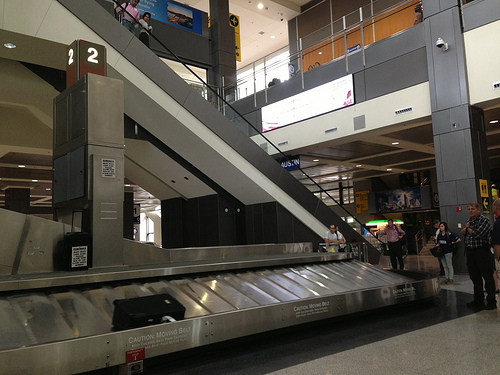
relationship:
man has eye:
[455, 201, 496, 310] [465, 205, 470, 212]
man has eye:
[455, 201, 496, 310] [470, 205, 477, 213]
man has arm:
[459, 201, 496, 310] [456, 217, 491, 234]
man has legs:
[455, 201, 496, 310] [464, 247, 495, 302]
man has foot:
[459, 201, 496, 310] [465, 297, 495, 314]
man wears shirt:
[459, 201, 496, 310] [457, 212, 497, 252]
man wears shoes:
[459, 201, 496, 310] [464, 296, 498, 312]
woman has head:
[437, 221, 456, 286] [437, 222, 447, 232]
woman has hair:
[437, 221, 456, 286] [427, 199, 450, 231]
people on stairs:
[324, 222, 349, 252] [274, 146, 493, 328]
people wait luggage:
[324, 202, 499, 309] [112, 292, 186, 331]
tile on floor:
[263, 267, 498, 372] [145, 256, 499, 373]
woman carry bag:
[429, 217, 456, 287] [426, 240, 450, 259]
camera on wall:
[424, 19, 459, 61] [422, 10, 465, 89]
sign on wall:
[252, 71, 363, 135] [235, 57, 376, 141]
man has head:
[459, 201, 496, 310] [466, 200, 481, 217]